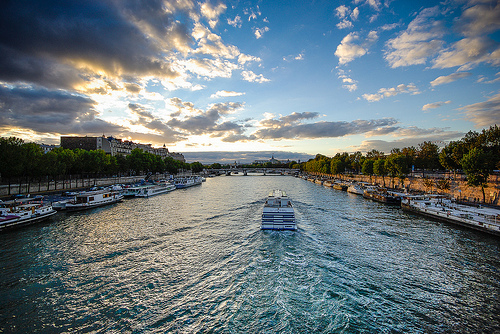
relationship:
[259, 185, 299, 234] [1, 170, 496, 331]
boat in center water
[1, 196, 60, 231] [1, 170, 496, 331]
boat in water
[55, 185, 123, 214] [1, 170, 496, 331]
boat in water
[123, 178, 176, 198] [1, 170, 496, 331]
boat in water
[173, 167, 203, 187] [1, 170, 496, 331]
boat in water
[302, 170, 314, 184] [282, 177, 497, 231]
boat parked on side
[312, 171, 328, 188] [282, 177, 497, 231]
boat parked on side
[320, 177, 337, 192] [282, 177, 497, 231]
boat parked on side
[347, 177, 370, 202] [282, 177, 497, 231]
boat parked on side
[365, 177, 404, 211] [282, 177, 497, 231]
boat parked on side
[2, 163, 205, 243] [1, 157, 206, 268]
boats parked on side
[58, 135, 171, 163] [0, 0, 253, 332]
buildings on left side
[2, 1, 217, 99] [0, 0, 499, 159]
cloud in sky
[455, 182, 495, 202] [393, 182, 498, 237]
dirt next to boats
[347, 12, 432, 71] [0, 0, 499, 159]
clouds in sky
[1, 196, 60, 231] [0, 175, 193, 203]
boat parked along bank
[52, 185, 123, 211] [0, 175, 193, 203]
boat parked along bank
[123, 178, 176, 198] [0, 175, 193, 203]
boat parked along bank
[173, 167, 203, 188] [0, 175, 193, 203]
boat parked along bank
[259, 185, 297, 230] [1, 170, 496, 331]
boat traveling in water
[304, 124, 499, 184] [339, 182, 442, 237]
trees along bank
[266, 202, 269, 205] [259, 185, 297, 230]
person on boat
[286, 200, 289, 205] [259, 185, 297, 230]
person on boat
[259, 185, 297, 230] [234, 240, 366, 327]
boat driving down water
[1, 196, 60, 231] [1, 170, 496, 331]
boat parked on water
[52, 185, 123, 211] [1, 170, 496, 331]
boat parked on water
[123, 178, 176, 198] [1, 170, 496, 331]
boat parked on water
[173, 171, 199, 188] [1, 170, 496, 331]
boat parked on water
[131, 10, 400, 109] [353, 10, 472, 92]
sky with clouds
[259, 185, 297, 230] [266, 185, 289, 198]
boat has section